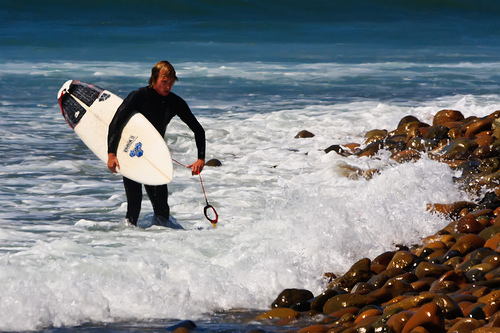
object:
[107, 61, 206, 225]
man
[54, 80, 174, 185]
surfboard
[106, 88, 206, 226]
suit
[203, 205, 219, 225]
handle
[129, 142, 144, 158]
logo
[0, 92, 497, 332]
foam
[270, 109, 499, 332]
shore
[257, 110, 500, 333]
rocks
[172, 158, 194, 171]
strap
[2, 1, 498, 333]
photo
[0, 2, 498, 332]
daytime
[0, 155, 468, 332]
wave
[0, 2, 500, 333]
ocean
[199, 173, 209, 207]
string